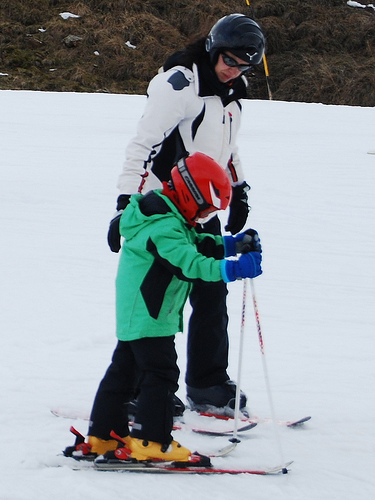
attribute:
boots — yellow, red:
[87, 426, 195, 465]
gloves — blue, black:
[220, 228, 265, 283]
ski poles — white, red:
[229, 245, 289, 480]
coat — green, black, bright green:
[110, 188, 224, 343]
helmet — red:
[170, 149, 233, 227]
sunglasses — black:
[219, 50, 251, 73]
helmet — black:
[205, 11, 265, 70]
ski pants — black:
[85, 332, 181, 442]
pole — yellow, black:
[246, 0, 275, 103]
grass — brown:
[1, 1, 374, 106]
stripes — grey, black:
[176, 156, 207, 209]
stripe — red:
[154, 463, 265, 475]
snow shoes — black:
[122, 378, 247, 419]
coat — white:
[114, 38, 249, 227]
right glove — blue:
[222, 251, 262, 282]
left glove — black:
[221, 173, 251, 237]